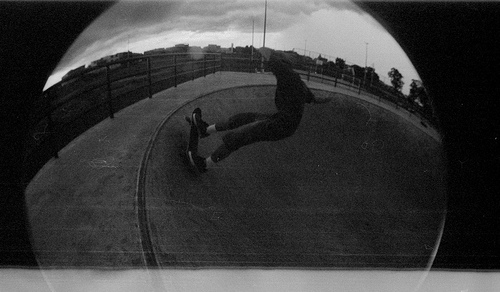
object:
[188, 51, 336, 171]
boy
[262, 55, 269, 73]
arm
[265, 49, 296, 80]
head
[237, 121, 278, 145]
thigh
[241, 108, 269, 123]
thigh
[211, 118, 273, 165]
leg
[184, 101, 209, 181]
skateboard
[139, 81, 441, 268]
ramp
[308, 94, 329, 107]
arm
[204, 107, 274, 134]
leg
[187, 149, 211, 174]
foot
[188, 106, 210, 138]
foot